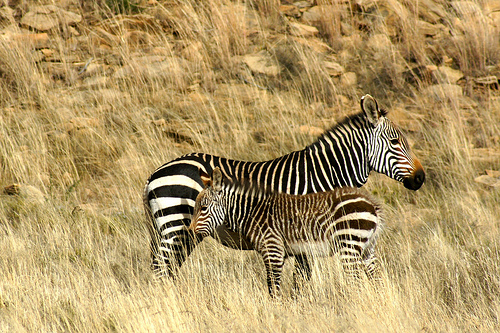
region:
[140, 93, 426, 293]
Two zebras in a field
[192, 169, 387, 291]
Young zebra beside adult zebra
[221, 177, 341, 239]
Brown part of zebra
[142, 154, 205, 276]
Black and white stripes on zebra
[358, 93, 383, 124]
Two small zebra's ears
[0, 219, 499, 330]
Brown long grass in field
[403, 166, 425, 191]
Black mouth of zebra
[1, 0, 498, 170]
Rocks in a field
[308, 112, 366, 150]
White and black mane of zebra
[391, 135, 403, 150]
One eye of zebra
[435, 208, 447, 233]
part of the grass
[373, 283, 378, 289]
tip of the grass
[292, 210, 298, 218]
part of a zebra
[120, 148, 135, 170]
part of a rock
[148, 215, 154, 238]
tail of a zebra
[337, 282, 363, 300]
part of a plantation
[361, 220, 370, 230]
back of a zebra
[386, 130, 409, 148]
eye of a zebra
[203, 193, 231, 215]
head of a zebra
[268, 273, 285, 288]
leg of a zebra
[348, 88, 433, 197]
head of the zebra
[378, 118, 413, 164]
eye of the zebra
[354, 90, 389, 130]
ear of the zebra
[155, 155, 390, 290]
baby zebra next to adult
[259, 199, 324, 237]
stripes on the zebra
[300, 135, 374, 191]
black and white animal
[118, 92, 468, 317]
two zebras next to each other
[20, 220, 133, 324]
white grass next to zebras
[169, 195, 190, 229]
shadow on the zebra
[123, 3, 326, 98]
grass in the background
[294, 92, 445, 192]
a black and white zebra head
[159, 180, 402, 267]
a baby zebra with the mother zebra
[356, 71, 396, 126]
a zebra big ear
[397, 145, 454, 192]
the nose of a zebra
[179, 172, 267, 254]
the head of a baby zebra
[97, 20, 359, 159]
a lot of brown tall grass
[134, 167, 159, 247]
tail of a zebra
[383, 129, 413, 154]
a xebra black eye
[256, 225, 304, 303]
baby zebra front leg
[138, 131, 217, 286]
a zebra hind leg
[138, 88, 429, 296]
adult zebra with young zebra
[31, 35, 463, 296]
tall beige grasses curving to side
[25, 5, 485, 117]
gray and tan rocks across slope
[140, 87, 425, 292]
zebras facing opposite directions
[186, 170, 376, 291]
tall blades of grass in front of young zebra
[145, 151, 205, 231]
bold and thick black and white stripes over rump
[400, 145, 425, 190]
rusty-brown marking on top of nose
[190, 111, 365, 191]
vertical stripes along neck and body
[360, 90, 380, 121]
oval ear with black center bordered in white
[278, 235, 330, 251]
rectagular patch of white in young zebra's underbelly